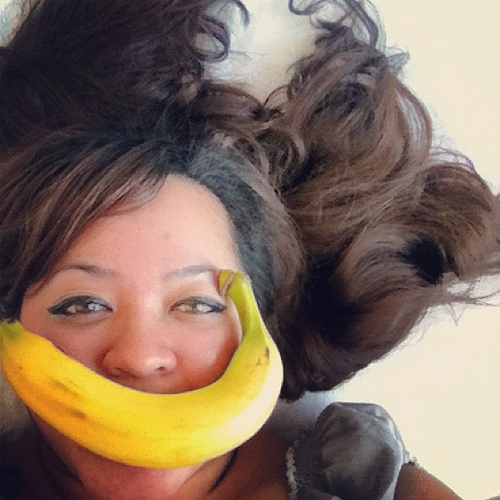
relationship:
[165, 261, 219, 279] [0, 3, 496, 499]
eyebrows of lady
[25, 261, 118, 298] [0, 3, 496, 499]
eyebrows of lady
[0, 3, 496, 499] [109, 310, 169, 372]
lady has nose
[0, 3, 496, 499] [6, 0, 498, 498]
lady lying on surface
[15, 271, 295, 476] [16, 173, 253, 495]
banana on woman's face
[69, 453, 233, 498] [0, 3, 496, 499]
chin of a lady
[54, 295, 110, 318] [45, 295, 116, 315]
eye have makeup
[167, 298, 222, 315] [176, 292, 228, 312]
eye have makeup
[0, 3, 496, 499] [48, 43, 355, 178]
lady has hair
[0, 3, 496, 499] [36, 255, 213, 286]
lady has eyebrows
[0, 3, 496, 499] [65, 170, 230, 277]
lady has forehead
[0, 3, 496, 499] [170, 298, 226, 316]
lady has eye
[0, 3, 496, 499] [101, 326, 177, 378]
lady has nose